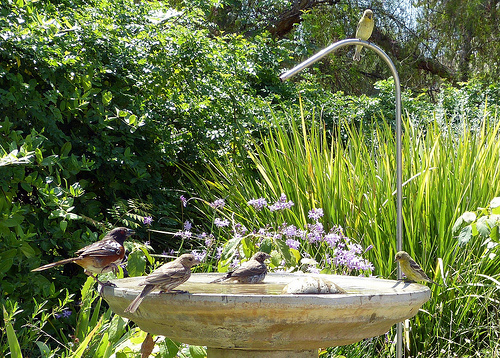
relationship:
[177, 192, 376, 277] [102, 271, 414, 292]
flower next to bath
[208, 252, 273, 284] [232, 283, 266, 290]
bird sitting in water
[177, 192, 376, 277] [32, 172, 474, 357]
flower behind faucet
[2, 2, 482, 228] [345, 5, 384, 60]
trees behind bird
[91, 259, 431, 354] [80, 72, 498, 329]
bird bath in garden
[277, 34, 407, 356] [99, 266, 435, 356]
pipe over birdbath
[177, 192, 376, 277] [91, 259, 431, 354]
flower growing over bird bath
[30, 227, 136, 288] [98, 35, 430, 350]
bird on bath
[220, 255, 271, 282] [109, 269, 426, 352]
bird bathing in bird bath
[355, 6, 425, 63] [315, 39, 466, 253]
bird sitting on pipe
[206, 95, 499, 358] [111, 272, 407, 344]
bushes behind bird bath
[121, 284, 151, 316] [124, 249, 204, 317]
tail on bird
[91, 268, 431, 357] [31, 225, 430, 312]
pool on bird bath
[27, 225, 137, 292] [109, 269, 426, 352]
bird on bird bath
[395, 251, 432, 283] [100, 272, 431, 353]
bird on bath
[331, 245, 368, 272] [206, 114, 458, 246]
flower in bushes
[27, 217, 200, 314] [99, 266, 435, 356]
birds in birdbath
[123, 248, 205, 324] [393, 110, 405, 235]
bird on pipe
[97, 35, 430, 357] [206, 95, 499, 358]
bath by bushes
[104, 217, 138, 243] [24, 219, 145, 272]
head on bird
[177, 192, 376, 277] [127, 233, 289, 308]
flower by birds